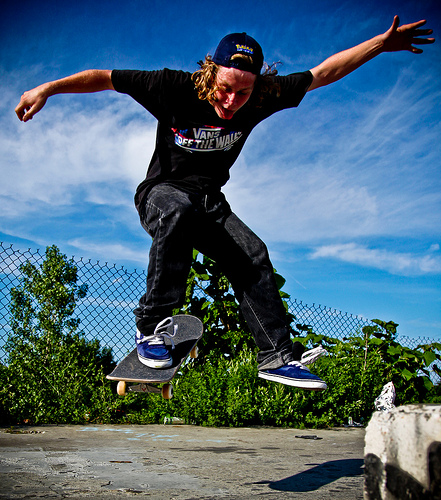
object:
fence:
[0, 244, 440, 388]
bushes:
[304, 316, 441, 424]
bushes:
[118, 247, 330, 426]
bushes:
[0, 241, 127, 426]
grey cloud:
[310, 243, 439, 277]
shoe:
[258, 361, 327, 389]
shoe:
[134, 327, 172, 369]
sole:
[137, 353, 173, 369]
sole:
[258, 372, 327, 389]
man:
[14, 15, 435, 392]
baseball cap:
[213, 32, 264, 73]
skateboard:
[105, 314, 203, 399]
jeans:
[133, 186, 292, 372]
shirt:
[111, 69, 313, 200]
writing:
[176, 127, 241, 152]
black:
[109, 316, 200, 378]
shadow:
[268, 458, 360, 492]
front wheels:
[116, 381, 125, 395]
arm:
[260, 34, 386, 119]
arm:
[47, 69, 180, 94]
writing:
[81, 424, 222, 442]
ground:
[0, 419, 364, 500]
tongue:
[219, 106, 234, 119]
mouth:
[222, 107, 234, 119]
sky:
[0, 0, 440, 358]